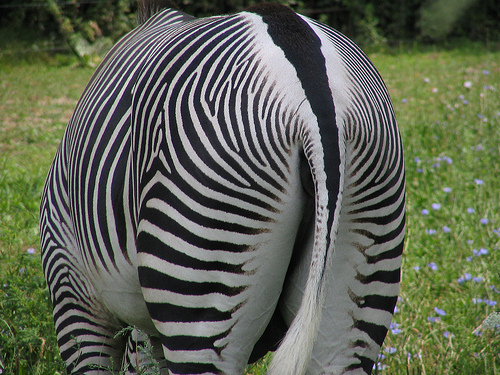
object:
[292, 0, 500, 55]
bushes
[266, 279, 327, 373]
edge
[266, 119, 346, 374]
tail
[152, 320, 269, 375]
back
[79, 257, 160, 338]
belly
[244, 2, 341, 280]
stripe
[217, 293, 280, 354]
veins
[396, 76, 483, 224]
field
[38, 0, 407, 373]
zebra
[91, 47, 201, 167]
stripes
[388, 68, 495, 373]
flowers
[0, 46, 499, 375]
grass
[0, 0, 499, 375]
garden